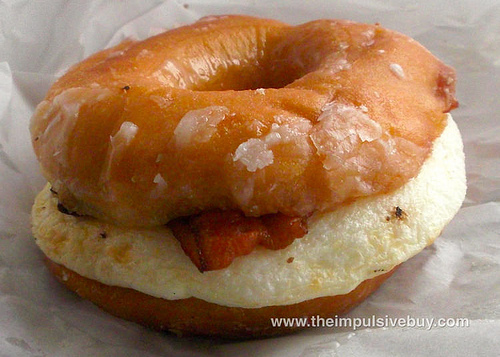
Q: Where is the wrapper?
A: Under the sandwich.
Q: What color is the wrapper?
A: White.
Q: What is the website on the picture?
A: www.theimpulsivebuy.com.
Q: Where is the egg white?
A: In the sandwich.